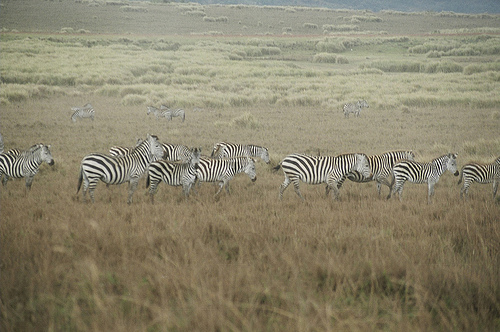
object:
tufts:
[140, 171, 153, 188]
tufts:
[71, 157, 82, 201]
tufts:
[207, 140, 219, 162]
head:
[37, 143, 57, 169]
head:
[143, 132, 168, 161]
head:
[187, 147, 202, 170]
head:
[241, 155, 260, 183]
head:
[260, 145, 272, 164]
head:
[352, 153, 374, 178]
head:
[406, 148, 416, 162]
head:
[441, 152, 460, 177]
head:
[359, 100, 369, 108]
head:
[156, 102, 163, 108]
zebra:
[108, 132, 160, 166]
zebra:
[197, 154, 257, 197]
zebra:
[210, 140, 271, 168]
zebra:
[326, 150, 415, 199]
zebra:
[455, 153, 500, 196]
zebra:
[341, 99, 369, 120]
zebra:
[140, 104, 171, 121]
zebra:
[70, 101, 94, 120]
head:
[146, 102, 151, 114]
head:
[70, 112, 77, 120]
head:
[82, 102, 92, 106]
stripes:
[283, 152, 360, 182]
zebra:
[339, 100, 365, 120]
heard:
[0, 95, 499, 205]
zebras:
[160, 104, 186, 123]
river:
[227, 9, 497, 45]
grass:
[0, 195, 500, 332]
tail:
[73, 171, 85, 197]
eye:
[366, 164, 371, 169]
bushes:
[0, 0, 497, 112]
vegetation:
[3, 2, 499, 130]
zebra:
[269, 151, 374, 199]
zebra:
[384, 152, 460, 205]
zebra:
[143, 144, 203, 203]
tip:
[70, 163, 92, 200]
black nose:
[453, 169, 459, 175]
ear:
[146, 133, 158, 145]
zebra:
[72, 133, 169, 201]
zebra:
[0, 142, 54, 194]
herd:
[73, 134, 460, 197]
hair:
[74, 171, 84, 193]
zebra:
[75, 134, 169, 206]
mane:
[132, 133, 153, 153]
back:
[80, 143, 157, 168]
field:
[6, 6, 481, 327]